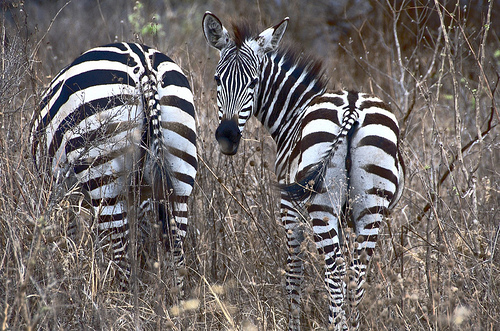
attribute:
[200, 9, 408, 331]
zebra — black, white, looking, young, wild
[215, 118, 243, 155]
nose — black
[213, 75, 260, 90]
eyes — dark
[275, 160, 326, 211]
hair — dark, black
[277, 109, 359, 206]
tail — black, white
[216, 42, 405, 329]
stripes — black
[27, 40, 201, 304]
zebra — black, white, wild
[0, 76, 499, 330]
grass — tall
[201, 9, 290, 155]
head — turning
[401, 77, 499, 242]
twig — dark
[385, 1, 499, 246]
branches — bare, dead, dry